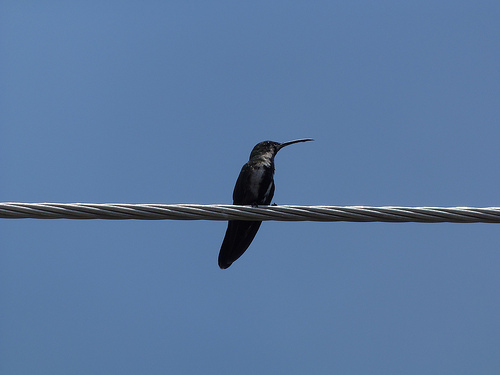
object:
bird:
[214, 133, 320, 273]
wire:
[0, 201, 497, 228]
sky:
[0, 1, 499, 375]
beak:
[278, 137, 313, 146]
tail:
[217, 219, 259, 271]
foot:
[251, 195, 263, 211]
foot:
[263, 198, 272, 209]